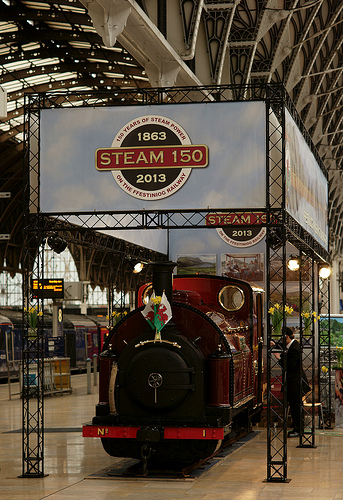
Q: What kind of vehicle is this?
A: Train.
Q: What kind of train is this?
A: Red and black.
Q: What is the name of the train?
A: Steam 150.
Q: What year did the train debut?
A: 1863.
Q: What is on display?
A: Train.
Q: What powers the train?
A: Steam.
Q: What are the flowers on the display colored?
A: Yellow.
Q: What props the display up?
A: Metal supports.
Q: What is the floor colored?
A: Brown.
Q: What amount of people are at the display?
A: One person.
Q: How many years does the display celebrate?
A: 150.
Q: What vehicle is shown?
A: Train.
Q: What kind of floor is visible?
A: Tile.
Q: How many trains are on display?
A: One.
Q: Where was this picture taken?
A: Train station.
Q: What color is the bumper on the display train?
A: Red.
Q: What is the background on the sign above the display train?
A: Clouds.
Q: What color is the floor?
A: Tan.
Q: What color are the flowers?
A: Yellow.